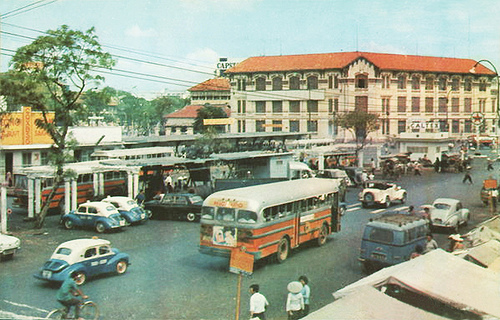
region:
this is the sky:
[209, 15, 286, 30]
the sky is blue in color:
[233, 5, 278, 27]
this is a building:
[260, 60, 455, 138]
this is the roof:
[381, 50, 446, 75]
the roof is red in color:
[394, 55, 436, 67]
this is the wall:
[373, 75, 398, 107]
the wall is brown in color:
[366, 82, 381, 100]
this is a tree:
[25, 34, 107, 132]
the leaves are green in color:
[47, 29, 82, 64]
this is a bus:
[240, 180, 329, 247]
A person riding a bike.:
[44, 269, 100, 319]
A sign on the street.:
[223, 243, 260, 318]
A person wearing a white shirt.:
[246, 280, 273, 319]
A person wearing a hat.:
[284, 275, 306, 318]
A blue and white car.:
[61, 200, 128, 235]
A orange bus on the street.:
[196, 175, 344, 265]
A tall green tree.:
[0, 23, 120, 229]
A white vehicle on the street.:
[357, 178, 411, 208]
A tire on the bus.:
[275, 231, 292, 262]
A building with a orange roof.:
[221, 52, 498, 154]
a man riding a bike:
[39, 270, 117, 311]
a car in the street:
[44, 215, 155, 283]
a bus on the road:
[200, 142, 414, 277]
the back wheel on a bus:
[254, 230, 301, 262]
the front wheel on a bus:
[304, 213, 346, 245]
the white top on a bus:
[200, 156, 372, 246]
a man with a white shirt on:
[243, 265, 289, 315]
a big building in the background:
[221, 40, 498, 151]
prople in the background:
[361, 150, 478, 190]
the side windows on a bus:
[256, 177, 364, 241]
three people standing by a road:
[232, 269, 312, 319]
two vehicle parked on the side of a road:
[358, 202, 455, 282]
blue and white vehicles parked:
[63, 194, 140, 234]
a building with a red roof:
[239, 39, 458, 95]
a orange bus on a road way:
[186, 167, 362, 293]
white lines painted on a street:
[334, 191, 421, 221]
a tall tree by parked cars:
[18, 22, 93, 240]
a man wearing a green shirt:
[48, 269, 84, 316]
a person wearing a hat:
[283, 277, 309, 304]